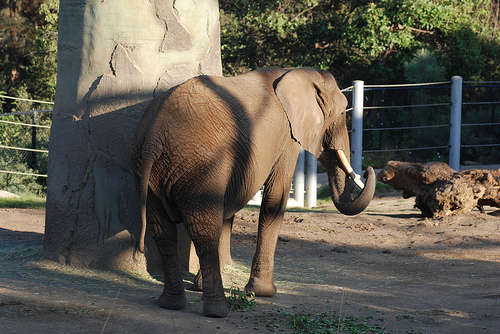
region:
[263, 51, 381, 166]
head of an elephant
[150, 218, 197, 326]
leg of an elephant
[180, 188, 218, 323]
leg of an elephant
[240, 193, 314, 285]
leg of an elephant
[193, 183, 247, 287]
leg of an elephant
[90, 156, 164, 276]
tail of an elephant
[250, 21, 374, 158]
ear of an elephant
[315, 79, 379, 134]
eye of an elephant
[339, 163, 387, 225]
nose of an elephant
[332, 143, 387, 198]
trunk of an elephant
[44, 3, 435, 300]
an elephant against a trunk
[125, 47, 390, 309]
the elephant is partly shaded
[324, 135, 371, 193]
this elephant has tusks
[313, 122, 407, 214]
the elephant's trunk is curved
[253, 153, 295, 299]
this elephant has a thin leg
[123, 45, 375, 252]
this elephant looks brown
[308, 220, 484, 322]
dirt on the ground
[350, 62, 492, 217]
a fence to contain the elephant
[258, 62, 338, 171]
this elephant has a big ear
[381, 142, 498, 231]
a wooden tree trunk in the cage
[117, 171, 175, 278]
tail of an elephant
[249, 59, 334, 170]
ear of an elephant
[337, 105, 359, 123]
eye of an elephant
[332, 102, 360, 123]
an eye of an elephant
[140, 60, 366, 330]
The elephant with its hind turned.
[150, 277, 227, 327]
The back hooves of the elephant.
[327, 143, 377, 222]
The elephants trunk.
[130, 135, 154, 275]
The elephants tail.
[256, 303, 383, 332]
The leaves on the ground.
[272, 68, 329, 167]
The elephants right ear.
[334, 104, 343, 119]
The elephants right eye.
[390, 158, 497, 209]
Large rock in the field.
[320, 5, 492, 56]
Trees in the background.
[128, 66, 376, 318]
A gray african elephant.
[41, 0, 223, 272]
A very large tree trunk.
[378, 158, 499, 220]
A piece of wood.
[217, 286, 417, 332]
Green leaves on ground.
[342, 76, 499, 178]
Part of exhibit fence.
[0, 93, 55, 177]
Gray colored fence wire.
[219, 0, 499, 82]
A background of trees.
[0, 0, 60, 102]
An area of trees.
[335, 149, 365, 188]
A pair of tusk.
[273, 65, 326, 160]
A large elephant ear.